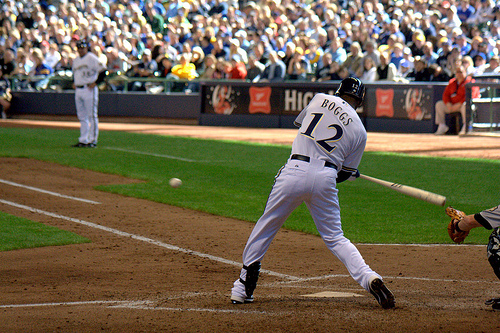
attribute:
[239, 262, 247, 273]
strap — black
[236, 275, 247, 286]
strap — black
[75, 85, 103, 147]
pants — white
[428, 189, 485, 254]
glove — baseball, left-handed, one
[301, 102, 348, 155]
number — 12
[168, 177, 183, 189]
baseball — flying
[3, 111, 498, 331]
field — dirt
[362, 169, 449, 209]
bat — one, baseball, swinging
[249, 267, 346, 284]
line — white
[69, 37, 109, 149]
coach — one, baseball, observant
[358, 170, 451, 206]
bat — brown, wooden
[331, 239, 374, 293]
shin — one, protected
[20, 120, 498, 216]
grass — green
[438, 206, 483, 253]
mitt — brown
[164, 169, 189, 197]
ball — baseball, base, airborne, flying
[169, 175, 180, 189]
baseball — white, flying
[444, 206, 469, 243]
catcher's mitt — light brown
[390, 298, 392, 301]
stud — exposed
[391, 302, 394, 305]
stud — exposed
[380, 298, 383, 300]
stud — exposed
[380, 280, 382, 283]
stud — exposed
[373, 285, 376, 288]
stud — exposed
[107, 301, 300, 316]
line — white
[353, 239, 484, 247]
line — white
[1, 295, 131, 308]
line — white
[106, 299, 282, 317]
line — white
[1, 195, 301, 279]
line — white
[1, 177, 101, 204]
line — white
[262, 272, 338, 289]
line — white